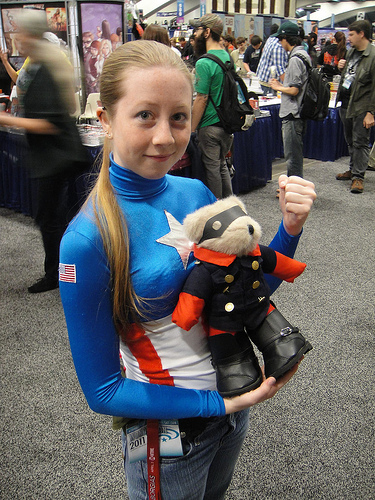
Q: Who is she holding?
A: Her doll.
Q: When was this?
A: Daytime.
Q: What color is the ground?
A: Grey.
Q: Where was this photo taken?
A: At a convention.